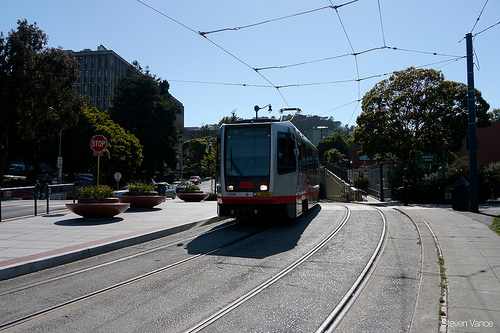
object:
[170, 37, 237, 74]
clouds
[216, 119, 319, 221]
car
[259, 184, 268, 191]
head light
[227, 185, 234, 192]
head light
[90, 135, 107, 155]
sign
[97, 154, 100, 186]
pole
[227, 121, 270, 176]
front window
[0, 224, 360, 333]
rail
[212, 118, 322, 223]
muni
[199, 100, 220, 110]
clouds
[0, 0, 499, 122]
blue sky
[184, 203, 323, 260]
shadow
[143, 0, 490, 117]
powerlines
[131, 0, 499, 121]
net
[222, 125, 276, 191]
windshield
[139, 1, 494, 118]
wire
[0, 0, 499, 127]
sky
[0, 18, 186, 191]
trees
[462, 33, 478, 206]
pole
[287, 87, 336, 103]
clouds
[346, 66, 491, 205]
cauliflower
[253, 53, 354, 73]
train wire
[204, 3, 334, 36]
train wire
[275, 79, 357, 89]
train wire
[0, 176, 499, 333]
street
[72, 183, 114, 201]
plant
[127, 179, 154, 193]
plant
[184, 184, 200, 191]
plant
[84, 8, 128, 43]
clouds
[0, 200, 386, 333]
tracks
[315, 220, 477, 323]
road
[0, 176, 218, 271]
side street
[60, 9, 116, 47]
clouds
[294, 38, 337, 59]
clouds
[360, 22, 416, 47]
clouds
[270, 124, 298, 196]
door